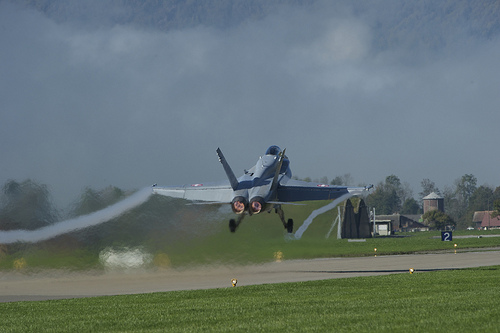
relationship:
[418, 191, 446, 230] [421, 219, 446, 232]
silo has base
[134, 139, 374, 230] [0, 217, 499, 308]
plane has runway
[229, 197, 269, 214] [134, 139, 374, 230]
burners are in back of plane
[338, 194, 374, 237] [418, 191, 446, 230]
sheds are beside silo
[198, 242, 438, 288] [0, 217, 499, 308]
lights are for runway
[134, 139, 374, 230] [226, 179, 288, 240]
plane has a tail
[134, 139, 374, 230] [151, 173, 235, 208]
plane has wing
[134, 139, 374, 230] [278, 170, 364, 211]
plane has wing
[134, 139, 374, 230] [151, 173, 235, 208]
plane has a wing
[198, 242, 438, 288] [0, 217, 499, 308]
lights are on runway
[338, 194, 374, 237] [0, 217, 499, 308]
sheds are beside runway